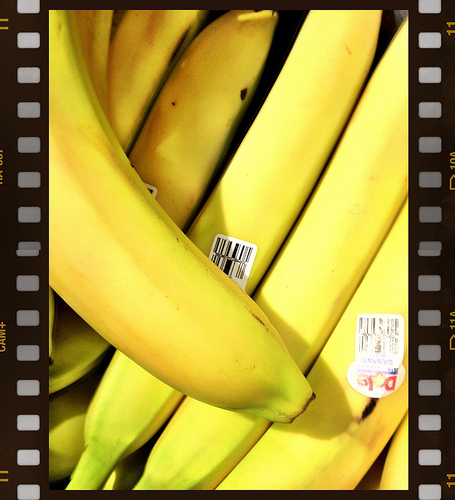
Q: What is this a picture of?
A: Bananas.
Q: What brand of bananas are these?
A: Dole.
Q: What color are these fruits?
A: Yellow.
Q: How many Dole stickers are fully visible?
A: One.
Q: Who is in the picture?
A: No one.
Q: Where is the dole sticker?
A: On a banana.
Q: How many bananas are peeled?
A: None.